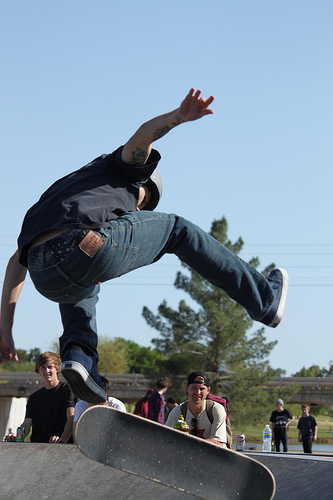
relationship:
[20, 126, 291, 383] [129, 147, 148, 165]
man has tattoo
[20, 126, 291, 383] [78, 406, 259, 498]
man on skateboard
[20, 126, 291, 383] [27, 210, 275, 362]
man wearing jeans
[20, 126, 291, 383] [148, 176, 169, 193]
man wearing cap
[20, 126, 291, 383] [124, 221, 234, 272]
man wearing jeans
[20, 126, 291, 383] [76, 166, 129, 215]
man wearing shirt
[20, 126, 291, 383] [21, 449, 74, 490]
man on ramp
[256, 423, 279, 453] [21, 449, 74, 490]
bottle on ramp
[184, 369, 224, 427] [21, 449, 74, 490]
boy on ramp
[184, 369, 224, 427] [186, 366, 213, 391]
boy wearing hat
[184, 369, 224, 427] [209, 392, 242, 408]
boy wearing backpack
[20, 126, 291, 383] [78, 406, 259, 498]
man riding skateboard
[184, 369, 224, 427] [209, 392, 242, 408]
boy has backpack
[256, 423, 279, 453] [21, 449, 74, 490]
bottle close to ramp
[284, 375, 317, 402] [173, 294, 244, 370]
tracks close tree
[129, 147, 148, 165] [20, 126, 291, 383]
tattoo close man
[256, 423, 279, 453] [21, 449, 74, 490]
bottle above ramp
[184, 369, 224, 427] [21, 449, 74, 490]
boy close to ramp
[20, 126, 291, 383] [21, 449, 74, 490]
man above ramp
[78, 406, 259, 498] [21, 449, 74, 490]
skateboard above ramp